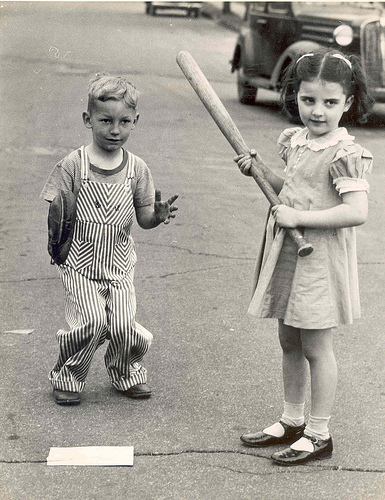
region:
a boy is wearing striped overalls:
[39, 70, 194, 411]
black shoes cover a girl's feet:
[227, 398, 356, 477]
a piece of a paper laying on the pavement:
[32, 420, 146, 482]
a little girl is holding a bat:
[179, 16, 368, 474]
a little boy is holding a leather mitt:
[27, 66, 182, 438]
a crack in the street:
[158, 438, 247, 464]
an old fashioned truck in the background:
[234, 0, 343, 79]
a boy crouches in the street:
[47, 74, 174, 428]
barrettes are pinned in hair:
[297, 52, 358, 67]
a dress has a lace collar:
[244, 130, 360, 338]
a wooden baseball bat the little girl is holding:
[170, 41, 316, 270]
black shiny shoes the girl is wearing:
[232, 405, 340, 466]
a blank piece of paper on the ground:
[41, 442, 143, 478]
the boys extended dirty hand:
[137, 183, 188, 235]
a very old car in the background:
[228, 4, 384, 118]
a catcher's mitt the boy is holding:
[42, 185, 80, 263]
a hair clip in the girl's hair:
[329, 52, 355, 77]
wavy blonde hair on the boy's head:
[96, 72, 141, 105]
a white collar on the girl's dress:
[288, 124, 356, 153]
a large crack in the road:
[146, 442, 241, 469]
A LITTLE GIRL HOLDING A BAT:
[170, 43, 377, 475]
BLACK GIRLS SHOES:
[235, 419, 348, 468]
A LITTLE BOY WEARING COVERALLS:
[43, 72, 187, 407]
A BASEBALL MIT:
[32, 182, 90, 268]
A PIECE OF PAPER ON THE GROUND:
[32, 438, 153, 477]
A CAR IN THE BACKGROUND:
[231, 4, 383, 129]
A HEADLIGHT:
[330, 17, 362, 50]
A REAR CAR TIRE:
[229, 32, 269, 107]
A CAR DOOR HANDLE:
[251, 15, 276, 29]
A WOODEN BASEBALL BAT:
[173, 49, 318, 262]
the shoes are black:
[227, 427, 345, 467]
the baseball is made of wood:
[227, 133, 316, 261]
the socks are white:
[272, 391, 340, 447]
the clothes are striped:
[46, 186, 135, 402]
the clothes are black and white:
[63, 174, 149, 385]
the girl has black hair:
[278, 30, 377, 118]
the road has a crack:
[96, 433, 290, 490]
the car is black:
[236, 14, 375, 53]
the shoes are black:
[54, 386, 167, 411]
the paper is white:
[53, 443, 141, 472]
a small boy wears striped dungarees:
[37, 70, 180, 404]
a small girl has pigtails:
[232, 46, 375, 467]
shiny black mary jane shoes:
[236, 418, 334, 464]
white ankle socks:
[262, 397, 334, 455]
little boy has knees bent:
[37, 70, 182, 404]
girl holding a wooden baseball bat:
[171, 45, 314, 259]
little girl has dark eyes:
[301, 94, 340, 108]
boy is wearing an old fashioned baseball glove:
[44, 185, 77, 267]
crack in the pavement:
[1, 447, 384, 478]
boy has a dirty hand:
[133, 182, 181, 229]